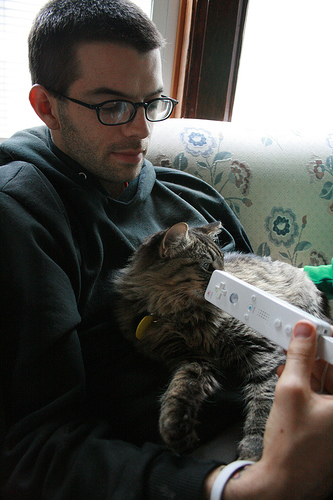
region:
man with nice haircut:
[17, 5, 166, 36]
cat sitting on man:
[155, 215, 277, 290]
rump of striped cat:
[229, 264, 321, 294]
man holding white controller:
[256, 295, 307, 353]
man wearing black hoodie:
[0, 398, 82, 446]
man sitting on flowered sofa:
[237, 169, 291, 177]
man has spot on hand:
[269, 418, 295, 450]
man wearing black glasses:
[73, 87, 228, 136]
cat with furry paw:
[174, 375, 183, 443]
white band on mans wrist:
[203, 464, 243, 498]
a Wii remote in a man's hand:
[201, 267, 331, 365]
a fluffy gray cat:
[102, 218, 332, 460]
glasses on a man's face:
[51, 88, 178, 124]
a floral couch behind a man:
[139, 118, 326, 275]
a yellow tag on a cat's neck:
[130, 311, 156, 340]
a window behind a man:
[154, 1, 251, 123]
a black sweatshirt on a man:
[0, 127, 254, 496]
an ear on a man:
[23, 79, 67, 141]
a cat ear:
[158, 216, 189, 255]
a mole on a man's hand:
[277, 424, 287, 438]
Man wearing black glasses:
[0, 0, 332, 499]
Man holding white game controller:
[1, 0, 332, 499]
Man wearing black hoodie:
[1, 0, 331, 498]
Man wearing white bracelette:
[0, 0, 331, 498]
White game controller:
[202, 266, 332, 363]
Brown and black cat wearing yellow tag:
[106, 218, 331, 460]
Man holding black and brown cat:
[0, 0, 331, 498]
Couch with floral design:
[136, 116, 331, 266]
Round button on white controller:
[273, 318, 282, 329]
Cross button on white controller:
[211, 282, 228, 300]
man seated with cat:
[20, 44, 277, 362]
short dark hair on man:
[34, 3, 161, 61]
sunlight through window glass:
[253, 20, 319, 107]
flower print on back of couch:
[197, 130, 304, 185]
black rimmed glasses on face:
[93, 90, 183, 129]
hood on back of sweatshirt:
[10, 119, 60, 172]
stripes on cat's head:
[196, 237, 225, 261]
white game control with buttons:
[201, 268, 289, 338]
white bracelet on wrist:
[210, 450, 252, 497]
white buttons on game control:
[264, 315, 293, 337]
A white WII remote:
[196, 257, 331, 371]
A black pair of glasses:
[40, 83, 179, 126]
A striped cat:
[108, 216, 328, 470]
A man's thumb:
[267, 309, 319, 402]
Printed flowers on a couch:
[144, 117, 330, 269]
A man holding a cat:
[2, 0, 328, 494]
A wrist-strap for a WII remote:
[186, 448, 267, 498]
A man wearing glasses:
[2, 3, 325, 496]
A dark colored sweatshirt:
[0, 120, 257, 499]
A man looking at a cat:
[0, 0, 331, 497]